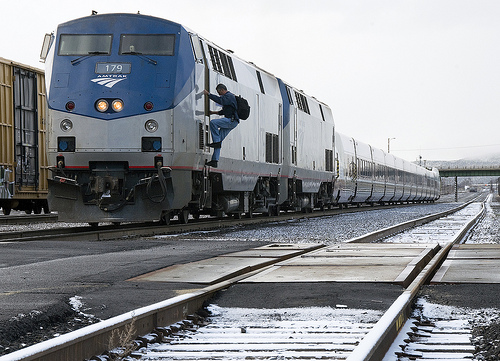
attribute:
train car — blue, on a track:
[333, 126, 353, 211]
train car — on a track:
[331, 132, 359, 207]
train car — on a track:
[356, 135, 373, 210]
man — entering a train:
[204, 82, 247, 168]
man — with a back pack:
[206, 83, 250, 167]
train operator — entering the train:
[203, 81, 249, 170]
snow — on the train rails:
[212, 293, 352, 358]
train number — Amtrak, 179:
[96, 60, 134, 74]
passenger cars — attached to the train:
[334, 132, 444, 205]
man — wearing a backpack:
[208, 82, 253, 167]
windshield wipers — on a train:
[69, 47, 158, 69]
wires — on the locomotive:
[146, 157, 171, 207]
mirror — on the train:
[39, 27, 55, 62]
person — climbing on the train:
[202, 82, 253, 168]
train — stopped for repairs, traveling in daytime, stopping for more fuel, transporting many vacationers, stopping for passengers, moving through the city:
[36, 11, 441, 221]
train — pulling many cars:
[38, 6, 338, 231]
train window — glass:
[112, 30, 180, 58]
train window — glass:
[56, 31, 112, 54]